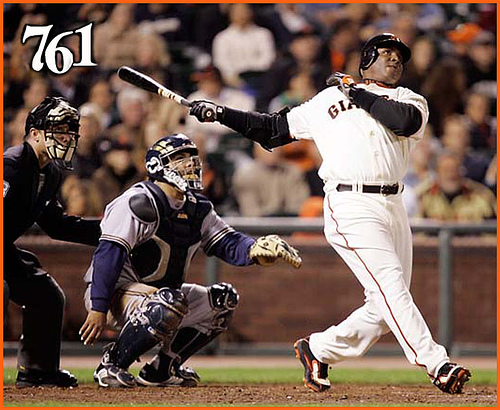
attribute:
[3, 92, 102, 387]
umpire — black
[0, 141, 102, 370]
uniform — black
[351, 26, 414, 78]
helmet — black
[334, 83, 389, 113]
lettering — black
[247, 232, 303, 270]
glove — brown, black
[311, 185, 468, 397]
pants — white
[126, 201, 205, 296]
pads — blue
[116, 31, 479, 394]
player — giant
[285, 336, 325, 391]
shoe — black, orange, white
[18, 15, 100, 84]
761 — white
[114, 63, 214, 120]
bat — black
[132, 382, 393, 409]
dirt — brown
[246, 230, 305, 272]
catchers mitt — leather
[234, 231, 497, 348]
wall — brown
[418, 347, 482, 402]
shoes — orange, white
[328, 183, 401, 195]
belt — black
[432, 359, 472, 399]
shoe — black, orange, white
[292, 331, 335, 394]
shoes — orange, white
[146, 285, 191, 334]
kneepads — blue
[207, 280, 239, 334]
kneepads — blue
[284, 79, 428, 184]
shirt — white, baseball